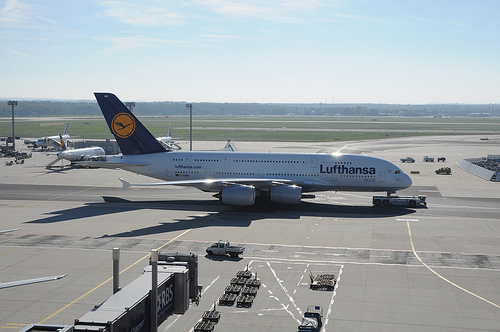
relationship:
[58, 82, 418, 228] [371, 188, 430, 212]
airplane being pulled by vehicle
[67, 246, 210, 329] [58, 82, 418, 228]
boarding walkway for airplane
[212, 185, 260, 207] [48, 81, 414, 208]
engine on airplane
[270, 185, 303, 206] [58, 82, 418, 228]
engine on airplane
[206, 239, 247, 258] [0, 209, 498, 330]
truck on tarmac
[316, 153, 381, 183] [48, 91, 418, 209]
name on plane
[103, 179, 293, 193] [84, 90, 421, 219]
wing on plane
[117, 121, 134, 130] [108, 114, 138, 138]
bird in circle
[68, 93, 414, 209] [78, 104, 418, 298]
airplane at airport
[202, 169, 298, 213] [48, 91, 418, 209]
turbines on plane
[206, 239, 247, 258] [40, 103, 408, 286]
truck at airport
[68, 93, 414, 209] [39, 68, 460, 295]
airplane at airport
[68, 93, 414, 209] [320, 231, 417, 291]
airplane on ground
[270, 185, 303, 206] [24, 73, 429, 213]
engine on plane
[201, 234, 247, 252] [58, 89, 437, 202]
truck driving plane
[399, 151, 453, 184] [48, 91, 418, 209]
vehicles beside plane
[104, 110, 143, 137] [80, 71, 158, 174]
circle on tail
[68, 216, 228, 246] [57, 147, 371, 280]
lines on runway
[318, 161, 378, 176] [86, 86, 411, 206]
word on plane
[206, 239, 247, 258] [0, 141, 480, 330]
truck on tarmac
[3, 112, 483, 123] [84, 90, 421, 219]
runway for plane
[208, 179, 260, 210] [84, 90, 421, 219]
engine on plane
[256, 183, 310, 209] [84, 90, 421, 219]
engine on plane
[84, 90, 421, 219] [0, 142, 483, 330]
plane on airway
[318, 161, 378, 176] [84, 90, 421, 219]
word on plane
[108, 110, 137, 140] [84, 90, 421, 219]
logo on plane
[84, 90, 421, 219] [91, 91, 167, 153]
plane has tail